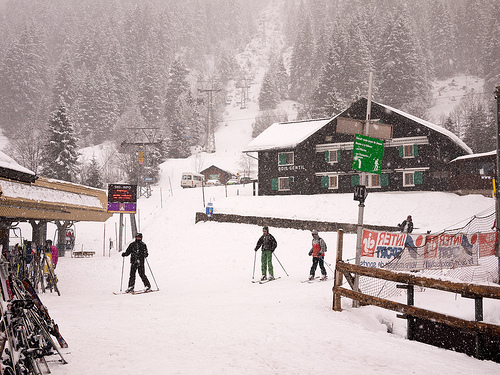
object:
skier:
[114, 230, 162, 295]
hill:
[57, 275, 179, 361]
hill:
[194, 232, 335, 345]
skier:
[300, 229, 335, 286]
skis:
[22, 277, 70, 348]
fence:
[332, 286, 500, 327]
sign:
[350, 133, 385, 175]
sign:
[106, 183, 139, 214]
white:
[156, 223, 250, 285]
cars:
[206, 179, 222, 186]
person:
[118, 232, 156, 292]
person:
[252, 224, 282, 282]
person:
[304, 227, 330, 280]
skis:
[131, 290, 155, 295]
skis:
[259, 277, 281, 284]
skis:
[308, 276, 329, 283]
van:
[180, 172, 206, 188]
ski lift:
[113, 126, 168, 198]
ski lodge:
[242, 95, 484, 195]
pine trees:
[258, 69, 279, 111]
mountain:
[2, 2, 482, 186]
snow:
[68, 298, 330, 375]